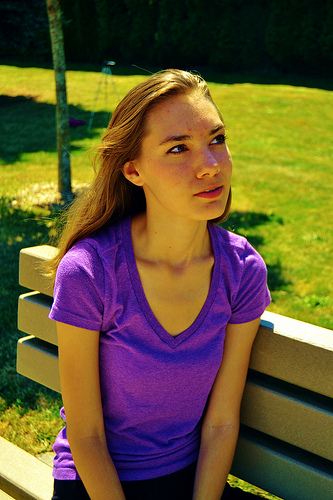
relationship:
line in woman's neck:
[151, 221, 206, 239] [143, 189, 207, 253]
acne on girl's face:
[184, 125, 198, 136] [136, 88, 235, 220]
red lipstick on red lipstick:
[191, 180, 225, 199] [193, 181, 223, 198]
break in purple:
[113, 318, 232, 365] [48, 221, 271, 482]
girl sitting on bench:
[40, 67, 270, 499] [0, 244, 332, 499]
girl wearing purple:
[40, 67, 270, 499] [48, 221, 271, 482]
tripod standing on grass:
[83, 57, 124, 130] [0, 53, 332, 499]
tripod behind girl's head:
[83, 57, 124, 130] [121, 65, 235, 222]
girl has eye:
[40, 67, 270, 499] [162, 143, 188, 156]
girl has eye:
[40, 67, 270, 499] [209, 131, 228, 146]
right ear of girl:
[116, 158, 145, 190] [40, 67, 270, 499]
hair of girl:
[44, 67, 233, 289] [40, 67, 270, 499]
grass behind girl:
[0, 53, 332, 499] [40, 67, 270, 499]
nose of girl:
[195, 140, 220, 180] [40, 67, 270, 499]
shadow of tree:
[0, 193, 282, 416] [49, 0, 72, 192]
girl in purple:
[40, 67, 270, 499] [49, 216, 274, 486]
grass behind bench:
[0, 53, 332, 499] [0, 244, 332, 499]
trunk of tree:
[49, 0, 72, 192] [264, 0, 330, 76]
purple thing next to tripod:
[67, 115, 83, 130] [83, 57, 124, 130]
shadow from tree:
[0, 193, 282, 416] [49, 0, 72, 192]